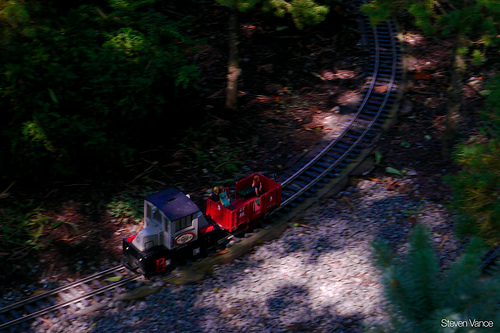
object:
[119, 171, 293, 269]
train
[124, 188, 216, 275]
engine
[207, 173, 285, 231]
car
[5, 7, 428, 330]
tracks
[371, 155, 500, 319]
trees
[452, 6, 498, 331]
right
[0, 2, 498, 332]
photo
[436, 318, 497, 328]
name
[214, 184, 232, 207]
people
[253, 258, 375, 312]
gravel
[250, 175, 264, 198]
little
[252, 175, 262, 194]
sitting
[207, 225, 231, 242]
piece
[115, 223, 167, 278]
front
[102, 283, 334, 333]
shadow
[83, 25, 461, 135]
ground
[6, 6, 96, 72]
leaves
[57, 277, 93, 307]
light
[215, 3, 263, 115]
tree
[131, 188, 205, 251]
cabin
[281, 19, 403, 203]
rail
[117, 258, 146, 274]
bumper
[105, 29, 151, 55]
flower